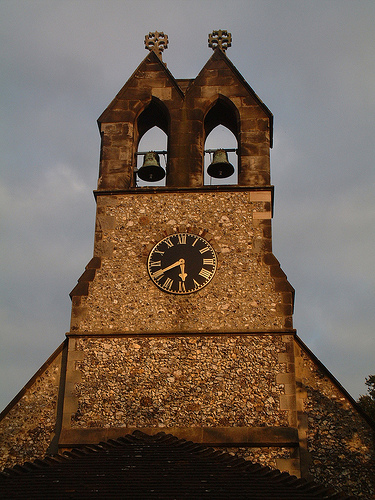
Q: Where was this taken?
A: Outside of a building.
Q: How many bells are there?
A: Two.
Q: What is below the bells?
A: A clock.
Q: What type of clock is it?
A: An analog clock.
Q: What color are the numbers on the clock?
A: Gold.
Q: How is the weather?
A: Cloudy.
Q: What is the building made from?
A: Stone.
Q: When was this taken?
A: During the evening.